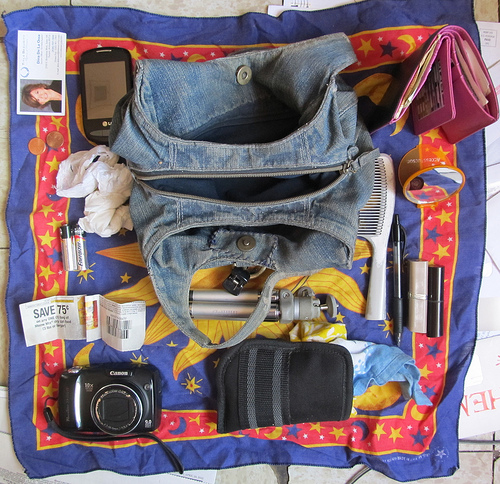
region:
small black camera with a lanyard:
[42, 358, 187, 478]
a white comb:
[353, 147, 396, 324]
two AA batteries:
[56, 219, 88, 272]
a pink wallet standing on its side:
[366, 25, 498, 146]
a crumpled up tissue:
[48, 143, 138, 237]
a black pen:
[385, 210, 405, 347]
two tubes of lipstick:
[403, 254, 443, 338]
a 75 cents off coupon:
[17, 291, 147, 353]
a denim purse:
[107, 29, 385, 351]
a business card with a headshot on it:
[13, 26, 68, 117]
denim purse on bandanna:
[135, 73, 304, 258]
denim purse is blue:
[142, 89, 388, 285]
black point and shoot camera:
[51, 344, 161, 454]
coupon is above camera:
[20, 299, 164, 379]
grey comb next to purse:
[340, 162, 388, 323]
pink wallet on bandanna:
[388, 32, 485, 152]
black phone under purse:
[76, 55, 133, 155]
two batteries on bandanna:
[58, 216, 107, 271]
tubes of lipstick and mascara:
[395, 254, 453, 355]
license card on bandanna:
[18, 32, 60, 128]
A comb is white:
[353, 151, 399, 320]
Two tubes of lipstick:
[403, 253, 447, 339]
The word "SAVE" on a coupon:
[30, 302, 58, 321]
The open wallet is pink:
[384, 22, 498, 150]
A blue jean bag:
[113, 29, 368, 354]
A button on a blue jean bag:
[229, 60, 254, 93]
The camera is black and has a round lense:
[37, 357, 189, 478]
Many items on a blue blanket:
[0, 0, 497, 480]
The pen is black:
[387, 210, 407, 350]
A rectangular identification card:
[12, 25, 70, 120]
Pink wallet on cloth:
[370, 25, 497, 141]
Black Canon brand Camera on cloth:
[40, 360, 180, 470]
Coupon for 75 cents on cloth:
[15, 290, 140, 345]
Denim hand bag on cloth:
[110, 30, 355, 345]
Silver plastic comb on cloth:
[355, 150, 385, 320]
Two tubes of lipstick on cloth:
[405, 255, 440, 335]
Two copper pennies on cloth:
[25, 130, 60, 155]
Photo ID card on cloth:
[15, 25, 65, 116]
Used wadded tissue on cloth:
[55, 145, 135, 235]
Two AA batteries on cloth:
[55, 221, 86, 268]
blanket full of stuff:
[15, 21, 470, 442]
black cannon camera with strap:
[42, 352, 159, 440]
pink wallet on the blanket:
[381, 20, 496, 140]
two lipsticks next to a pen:
[391, 215, 444, 339]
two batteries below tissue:
[55, 195, 110, 268]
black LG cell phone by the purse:
[76, 45, 135, 142]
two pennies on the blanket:
[22, 130, 68, 158]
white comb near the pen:
[360, 147, 405, 317]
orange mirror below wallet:
[400, 116, 460, 205]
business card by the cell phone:
[15, 27, 69, 117]